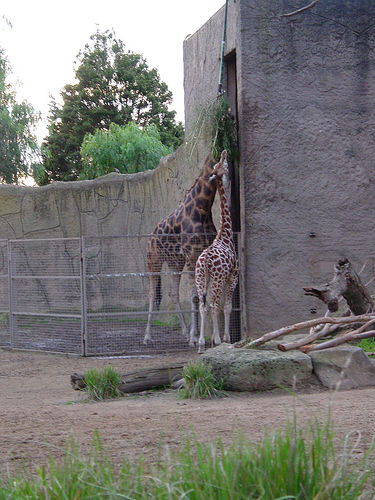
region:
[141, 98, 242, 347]
these are two giraffes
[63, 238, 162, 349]
this is a fence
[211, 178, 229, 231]
the neck is thin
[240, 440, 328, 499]
this is the grass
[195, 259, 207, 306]
this is the tail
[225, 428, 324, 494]
the grass are green n color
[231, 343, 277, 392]
this is a rock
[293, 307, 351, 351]
these are some woods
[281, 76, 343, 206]
this is a wall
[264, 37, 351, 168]
the wall is tall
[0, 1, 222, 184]
light sky of daytime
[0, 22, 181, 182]
three green tree tops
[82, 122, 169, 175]
green leaves on trees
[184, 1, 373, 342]
building of zoo enclosure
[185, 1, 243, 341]
door of zoo building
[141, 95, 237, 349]
two giraffes eating grass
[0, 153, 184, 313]
wall of zoo enclosure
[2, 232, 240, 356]
poles on chain link fence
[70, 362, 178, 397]
hoizontal log and grass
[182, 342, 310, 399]
rock and patch of grass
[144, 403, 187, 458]
part of a ground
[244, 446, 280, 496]
part of a grass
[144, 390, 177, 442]
part of a ground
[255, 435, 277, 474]
part of a grass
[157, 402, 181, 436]
part of a ground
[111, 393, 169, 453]
part of a ground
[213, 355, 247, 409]
part of a stone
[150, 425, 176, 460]
part of a ground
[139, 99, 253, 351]
Two giraffes eat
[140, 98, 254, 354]
Two giraffes on opposite sides of the enclosure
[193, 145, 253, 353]
A baby giraffe tries to reach the food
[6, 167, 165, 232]
Cracks in the stone wall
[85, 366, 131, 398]
A clump of grass near a log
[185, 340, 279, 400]
A clump of grass near stone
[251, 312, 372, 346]
A pile of small logs on stone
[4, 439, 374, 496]
Grass in the foreground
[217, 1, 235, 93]
A metal pole hangs along the stone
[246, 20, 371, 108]
Textured stone wall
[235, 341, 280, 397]
part of a stone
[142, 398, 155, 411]
part of a ground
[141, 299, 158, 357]
part of a fence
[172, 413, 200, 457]
part of a ground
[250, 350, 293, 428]
part of a roack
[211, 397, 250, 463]
part of a ground